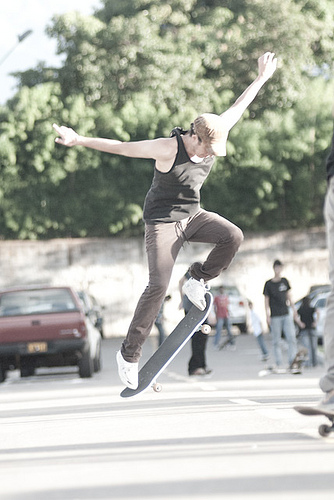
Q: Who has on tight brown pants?
A: Skater.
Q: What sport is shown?
A: Skateboarding.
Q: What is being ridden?
A: Skateboards.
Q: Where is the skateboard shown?
A: In the air.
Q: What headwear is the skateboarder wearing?
A: A baseball cap.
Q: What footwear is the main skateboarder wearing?
A: Tennis shoes.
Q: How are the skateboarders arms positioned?
A: Stretched out.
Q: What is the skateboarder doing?
A: Performing a trick.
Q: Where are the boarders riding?
A: A parking lot.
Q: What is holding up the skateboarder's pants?
A: Drawstrings.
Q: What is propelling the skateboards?
A: Wheel chocks.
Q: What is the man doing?
A: Skateboarding.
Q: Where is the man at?
A: Parking lot.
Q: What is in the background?
A: Cars.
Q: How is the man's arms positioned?
A: Spread eagle.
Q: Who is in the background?
A: Skateboarders.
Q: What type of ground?
A: Concrete.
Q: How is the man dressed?
A: Casual.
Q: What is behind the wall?
A: Trees.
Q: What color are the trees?
A: Green.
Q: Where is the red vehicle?
A: On the road.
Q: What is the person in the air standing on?
A: A skateboard.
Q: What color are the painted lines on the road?
A: White.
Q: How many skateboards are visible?
A: Four.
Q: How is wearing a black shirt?
A: The closest person.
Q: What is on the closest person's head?
A: A hat.